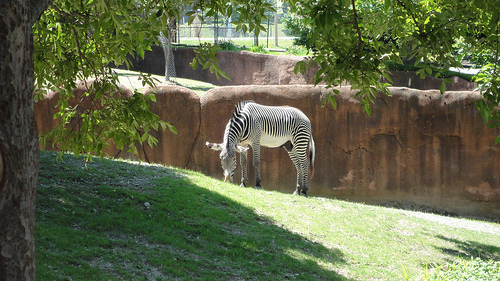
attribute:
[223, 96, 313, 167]
zebra — white, black, standing, eating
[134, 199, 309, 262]
grass — green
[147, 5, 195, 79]
trees — green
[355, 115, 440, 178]
rock — huge, brown